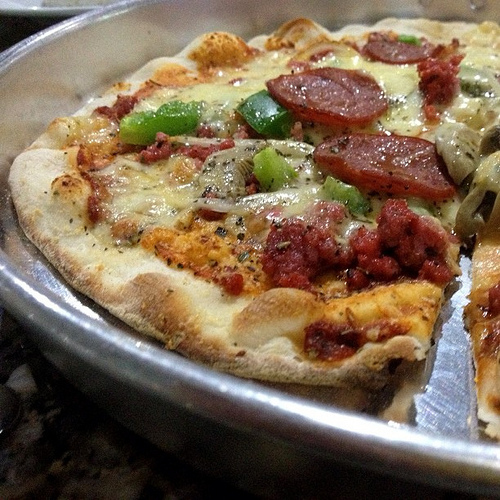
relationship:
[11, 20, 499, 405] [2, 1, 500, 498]
pizza in pan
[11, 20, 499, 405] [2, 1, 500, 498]
pizza on pan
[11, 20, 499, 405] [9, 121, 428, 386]
pizza has crust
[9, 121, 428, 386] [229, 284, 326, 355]
crust has a bubble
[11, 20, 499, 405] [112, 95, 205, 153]
pizza has peppers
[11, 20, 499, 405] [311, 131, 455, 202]
pizza has sausage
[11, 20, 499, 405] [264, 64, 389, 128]
pizza has pepperoni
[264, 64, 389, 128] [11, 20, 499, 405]
pepperoni on pizza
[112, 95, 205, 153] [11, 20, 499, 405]
peppers on pizza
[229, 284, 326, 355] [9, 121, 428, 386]
bubble on crust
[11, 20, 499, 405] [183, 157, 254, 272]
pizza has seasoning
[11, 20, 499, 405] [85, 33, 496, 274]
pizza has cheese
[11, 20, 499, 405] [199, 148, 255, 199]
pizza has mushrooms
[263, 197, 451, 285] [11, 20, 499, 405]
sauce on pizza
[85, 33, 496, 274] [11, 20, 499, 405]
cheese on pizza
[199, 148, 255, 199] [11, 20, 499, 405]
mushrooms on pizza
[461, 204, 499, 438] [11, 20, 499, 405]
slice not attached to pizza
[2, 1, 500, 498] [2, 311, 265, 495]
pan on counter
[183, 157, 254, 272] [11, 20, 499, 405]
specks on pizza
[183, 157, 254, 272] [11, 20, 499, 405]
seasoning on pizza